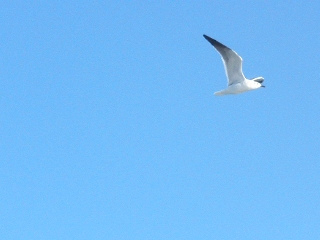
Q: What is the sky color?
A: Blue.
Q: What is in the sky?
A: Bird.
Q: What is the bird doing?
A: Flying.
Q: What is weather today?
A: Sunny day light sky.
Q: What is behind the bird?
A: Blue sky.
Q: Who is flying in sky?
A: The bird.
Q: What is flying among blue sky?
A: The bird.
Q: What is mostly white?
A: The bird.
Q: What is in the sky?
A: White bird with black tips.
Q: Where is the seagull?
A: In the air.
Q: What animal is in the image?
A: Bird.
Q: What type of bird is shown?
A: Seagull.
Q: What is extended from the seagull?
A: Wings.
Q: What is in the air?
A: Bird.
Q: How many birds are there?
A: One.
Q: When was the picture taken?
A: Daytime.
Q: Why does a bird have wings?
A: To fly.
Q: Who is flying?
A: A bird.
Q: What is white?
A: The bird.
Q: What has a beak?
A: A flying bird.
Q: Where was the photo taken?
A: In the sky.